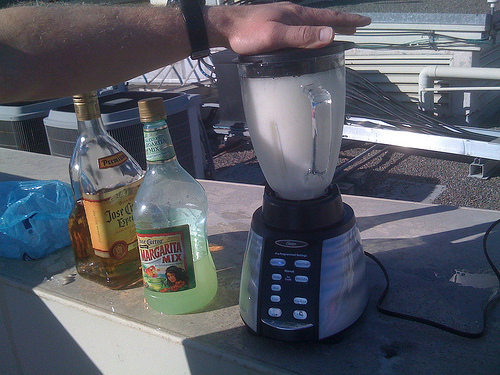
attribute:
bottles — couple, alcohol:
[46, 79, 226, 320]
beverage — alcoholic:
[57, 92, 139, 288]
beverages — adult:
[224, 71, 359, 197]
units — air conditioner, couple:
[6, 94, 207, 171]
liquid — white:
[248, 81, 307, 147]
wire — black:
[356, 197, 498, 351]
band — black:
[182, 11, 210, 56]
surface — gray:
[212, 208, 498, 369]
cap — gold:
[134, 101, 167, 120]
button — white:
[270, 255, 284, 266]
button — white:
[291, 250, 314, 273]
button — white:
[270, 272, 284, 281]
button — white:
[270, 284, 284, 293]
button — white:
[272, 293, 284, 301]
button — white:
[289, 294, 312, 305]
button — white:
[269, 306, 281, 318]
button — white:
[290, 306, 311, 326]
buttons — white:
[268, 257, 285, 319]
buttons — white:
[290, 255, 313, 327]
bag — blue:
[8, 181, 79, 262]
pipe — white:
[422, 66, 478, 113]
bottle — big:
[68, 90, 149, 286]